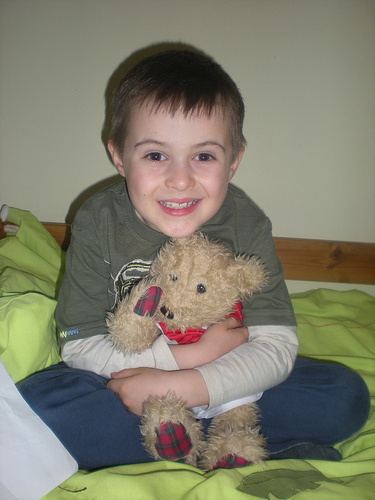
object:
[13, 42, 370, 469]
boy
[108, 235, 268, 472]
teddy bear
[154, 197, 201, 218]
smile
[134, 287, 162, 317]
plaid paw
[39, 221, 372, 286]
frame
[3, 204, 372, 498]
sheets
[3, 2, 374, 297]
wall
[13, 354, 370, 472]
jeans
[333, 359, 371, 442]
knee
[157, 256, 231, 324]
face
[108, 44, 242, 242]
head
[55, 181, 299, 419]
long sleeved shirt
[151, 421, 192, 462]
red plaid foot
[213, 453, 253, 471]
red plaid foot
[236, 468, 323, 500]
green leaf pattern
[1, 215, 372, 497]
bed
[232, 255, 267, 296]
ear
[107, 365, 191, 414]
hand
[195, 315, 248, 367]
hand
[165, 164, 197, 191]
nose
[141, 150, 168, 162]
eye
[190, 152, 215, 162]
eye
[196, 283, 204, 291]
eye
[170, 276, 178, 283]
eye